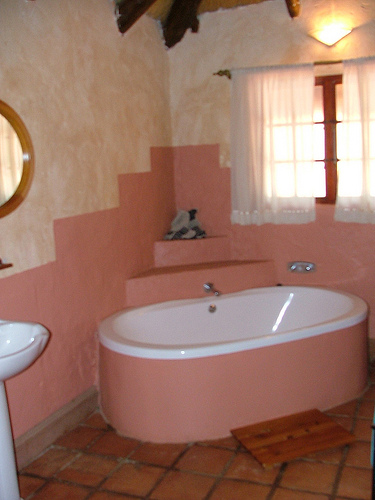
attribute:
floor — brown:
[14, 362, 374, 498]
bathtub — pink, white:
[97, 284, 368, 445]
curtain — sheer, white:
[229, 55, 375, 223]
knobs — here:
[290, 260, 315, 275]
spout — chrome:
[203, 282, 219, 297]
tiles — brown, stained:
[20, 364, 375, 499]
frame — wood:
[312, 72, 343, 206]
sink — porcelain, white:
[2, 318, 50, 500]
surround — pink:
[5, 143, 375, 440]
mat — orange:
[231, 405, 357, 473]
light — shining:
[268, 93, 364, 192]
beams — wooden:
[114, 2, 203, 49]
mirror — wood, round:
[3, 97, 37, 217]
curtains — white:
[231, 55, 375, 229]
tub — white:
[95, 281, 366, 444]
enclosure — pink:
[2, 145, 372, 438]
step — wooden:
[232, 404, 359, 471]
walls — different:
[2, 0, 373, 442]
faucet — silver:
[202, 281, 221, 299]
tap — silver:
[202, 277, 222, 298]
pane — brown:
[312, 71, 346, 206]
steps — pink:
[124, 233, 274, 307]